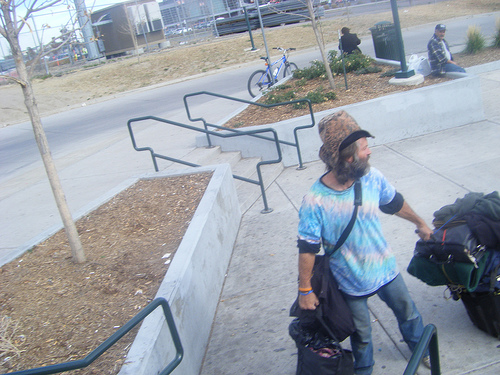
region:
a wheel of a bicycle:
[244, 67, 274, 94]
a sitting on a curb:
[430, 24, 458, 77]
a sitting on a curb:
[339, 27, 363, 49]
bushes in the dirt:
[267, 89, 332, 107]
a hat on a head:
[315, 108, 381, 140]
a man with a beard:
[315, 105, 380, 183]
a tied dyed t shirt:
[308, 186, 400, 285]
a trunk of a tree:
[53, 196, 96, 263]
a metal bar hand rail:
[121, 296, 198, 373]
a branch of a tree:
[21, 1, 41, 31]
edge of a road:
[207, 288, 223, 315]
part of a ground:
[106, 262, 126, 284]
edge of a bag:
[422, 235, 453, 261]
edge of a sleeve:
[290, 236, 321, 266]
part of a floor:
[240, 295, 268, 326]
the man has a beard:
[286, 100, 411, 203]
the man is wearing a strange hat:
[295, 98, 391, 181]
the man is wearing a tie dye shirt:
[301, 165, 435, 320]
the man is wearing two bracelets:
[277, 285, 350, 302]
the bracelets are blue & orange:
[289, 282, 316, 302]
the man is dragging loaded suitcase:
[403, 179, 498, 346]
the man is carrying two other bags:
[286, 234, 366, 371]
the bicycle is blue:
[240, 36, 312, 93]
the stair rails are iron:
[124, 84, 320, 187]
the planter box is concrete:
[5, 150, 239, 372]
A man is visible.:
[276, 151, 426, 372]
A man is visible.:
[243, 121, 376, 368]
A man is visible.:
[313, 145, 376, 369]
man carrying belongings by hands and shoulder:
[287, 109, 498, 374]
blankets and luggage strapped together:
[406, 191, 496, 336]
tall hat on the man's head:
[317, 110, 374, 167]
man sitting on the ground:
[426, 24, 468, 79]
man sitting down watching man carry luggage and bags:
[427, 23, 469, 80]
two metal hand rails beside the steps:
[126, 90, 315, 214]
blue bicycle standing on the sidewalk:
[246, 45, 298, 99]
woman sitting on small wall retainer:
[337, 25, 361, 58]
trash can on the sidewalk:
[370, 21, 395, 63]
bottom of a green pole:
[390, 0, 416, 80]